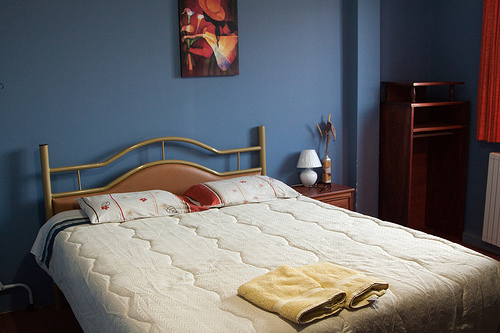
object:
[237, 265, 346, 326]
towels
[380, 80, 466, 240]
tall furniture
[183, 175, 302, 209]
pillow case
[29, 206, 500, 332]
bedspread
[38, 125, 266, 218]
headboard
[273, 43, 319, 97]
blue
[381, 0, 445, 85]
wall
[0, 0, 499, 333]
bedroom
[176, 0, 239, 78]
painting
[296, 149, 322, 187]
lamp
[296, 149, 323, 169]
lamp shade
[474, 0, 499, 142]
curtain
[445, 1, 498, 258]
wall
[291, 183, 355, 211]
side table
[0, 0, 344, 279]
wall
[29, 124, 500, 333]
bed